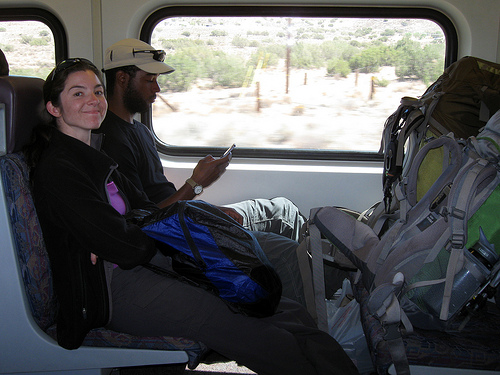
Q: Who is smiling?
A: The woman.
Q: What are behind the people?
A: The woman.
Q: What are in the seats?
A: Back packs.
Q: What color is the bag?
A: Black and blue.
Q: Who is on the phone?
A: The man.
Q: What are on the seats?
A: Cushioned.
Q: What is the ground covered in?
A: Sand.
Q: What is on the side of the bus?
A: Window.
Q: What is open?
A: The window.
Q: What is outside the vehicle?
A: Trees.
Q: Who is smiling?
A: The woman.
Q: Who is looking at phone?
A: The man.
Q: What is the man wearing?
A: A hat.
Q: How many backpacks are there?
A: Two.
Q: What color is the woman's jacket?
A: Black.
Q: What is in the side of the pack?
A: Water bottle.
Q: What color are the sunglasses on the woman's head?
A: Black.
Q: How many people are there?
A: Two.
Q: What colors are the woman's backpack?
A: Black and Blue.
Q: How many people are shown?
A: 2.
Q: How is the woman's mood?
A: Happy.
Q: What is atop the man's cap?
A: Sunglasses.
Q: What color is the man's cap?
A: White.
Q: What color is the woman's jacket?
A: Black.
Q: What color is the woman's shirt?
A: Purple.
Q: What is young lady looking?
A: Camera.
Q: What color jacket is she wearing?
A: Black.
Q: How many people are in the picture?
A: 2.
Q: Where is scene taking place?
A: On train.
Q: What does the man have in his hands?
A: Cell phone.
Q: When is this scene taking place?
A: Day time.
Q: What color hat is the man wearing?
A: White.